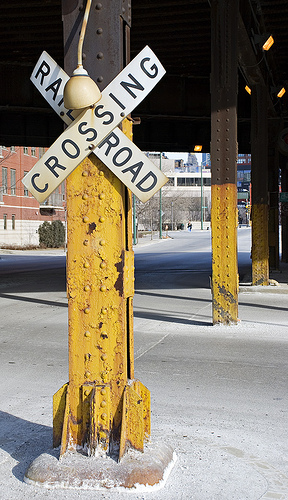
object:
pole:
[52, 0, 152, 460]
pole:
[207, 1, 242, 327]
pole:
[249, 7, 272, 285]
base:
[26, 439, 174, 490]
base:
[238, 275, 287, 296]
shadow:
[2, 409, 60, 484]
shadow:
[134, 308, 213, 335]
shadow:
[1, 294, 67, 315]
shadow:
[238, 301, 287, 317]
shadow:
[135, 288, 214, 308]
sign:
[19, 43, 169, 202]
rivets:
[84, 238, 91, 249]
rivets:
[98, 192, 106, 203]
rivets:
[99, 284, 108, 294]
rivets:
[98, 51, 105, 60]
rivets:
[84, 329, 93, 341]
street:
[0, 228, 287, 500]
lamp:
[259, 35, 277, 51]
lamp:
[276, 85, 286, 102]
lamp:
[242, 83, 251, 97]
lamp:
[190, 144, 203, 154]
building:
[0, 148, 67, 249]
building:
[134, 149, 218, 235]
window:
[10, 168, 19, 196]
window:
[0, 166, 10, 203]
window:
[9, 213, 18, 233]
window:
[22, 147, 33, 159]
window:
[177, 176, 185, 187]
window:
[187, 177, 197, 187]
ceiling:
[1, 1, 286, 154]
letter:
[94, 105, 117, 128]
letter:
[121, 72, 143, 98]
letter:
[142, 56, 159, 80]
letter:
[30, 173, 50, 195]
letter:
[44, 156, 68, 177]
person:
[186, 221, 193, 232]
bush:
[38, 220, 54, 251]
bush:
[51, 219, 67, 249]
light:
[61, 1, 100, 113]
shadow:
[1, 262, 253, 293]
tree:
[135, 200, 155, 245]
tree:
[164, 186, 189, 233]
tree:
[181, 195, 200, 228]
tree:
[237, 205, 247, 228]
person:
[179, 223, 186, 231]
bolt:
[80, 167, 89, 180]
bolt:
[81, 194, 90, 203]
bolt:
[225, 194, 230, 202]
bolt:
[227, 127, 231, 133]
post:
[197, 165, 205, 232]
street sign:
[201, 205, 209, 210]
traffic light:
[246, 200, 254, 212]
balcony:
[39, 198, 66, 210]